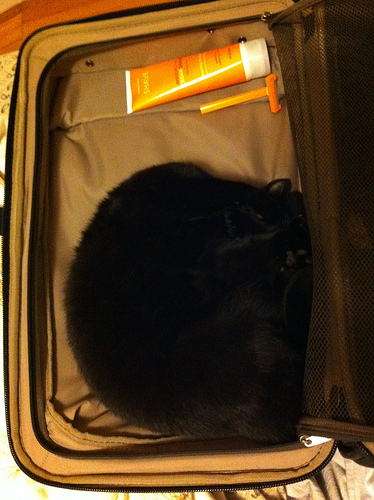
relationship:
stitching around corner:
[48, 376, 129, 443] [19, 339, 134, 472]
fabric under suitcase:
[3, 434, 176, 497] [0, 1, 359, 494]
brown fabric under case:
[316, 452, 361, 491] [0, 2, 372, 490]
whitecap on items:
[236, 38, 273, 80] [124, 37, 281, 112]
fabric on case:
[309, 6, 373, 422] [0, 0, 374, 500]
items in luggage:
[124, 37, 281, 112] [10, 4, 369, 359]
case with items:
[0, 0, 374, 500] [103, 36, 307, 147]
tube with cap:
[123, 38, 280, 109] [231, 31, 274, 82]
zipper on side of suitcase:
[2, 437, 349, 497] [0, 1, 359, 494]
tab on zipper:
[305, 434, 331, 444] [12, 443, 372, 493]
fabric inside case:
[266, 0, 373, 445] [0, 0, 374, 500]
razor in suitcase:
[195, 63, 287, 135] [0, 1, 359, 494]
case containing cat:
[0, 0, 374, 500] [57, 159, 317, 456]